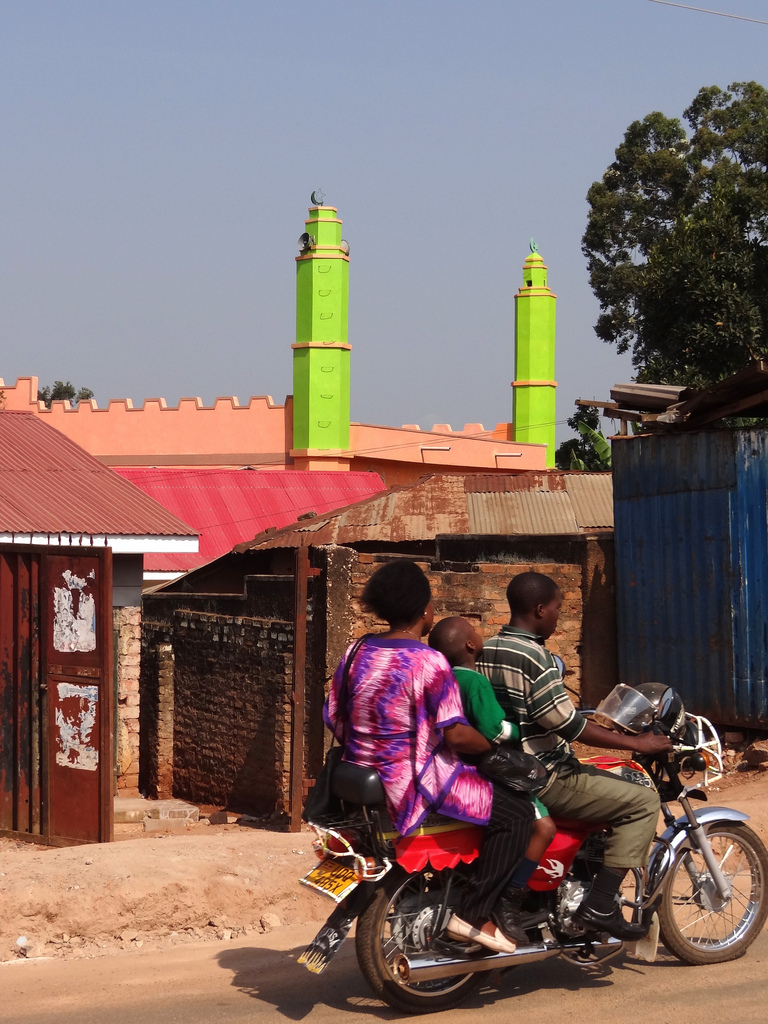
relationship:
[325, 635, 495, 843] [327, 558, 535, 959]
dress on woman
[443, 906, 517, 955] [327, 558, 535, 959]
loafer on woman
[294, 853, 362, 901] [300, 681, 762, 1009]
yellow plate on bike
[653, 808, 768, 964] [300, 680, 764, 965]
front tire on bike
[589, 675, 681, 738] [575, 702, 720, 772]
helmet on handlebars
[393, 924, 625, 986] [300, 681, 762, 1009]
exhaust on bike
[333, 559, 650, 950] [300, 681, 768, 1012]
people riding bike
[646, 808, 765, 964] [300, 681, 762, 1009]
front tire of bike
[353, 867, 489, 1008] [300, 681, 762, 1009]
back tire of bike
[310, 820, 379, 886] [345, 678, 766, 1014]
light of bike